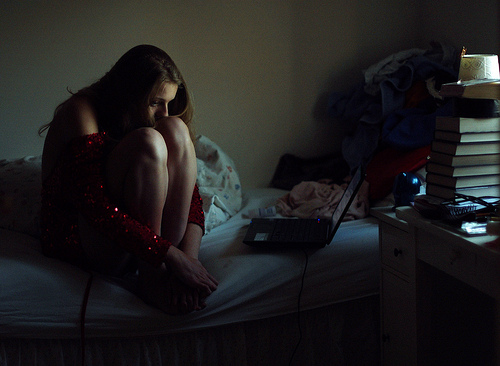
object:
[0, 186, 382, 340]
bed sheet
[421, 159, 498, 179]
books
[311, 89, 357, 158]
shade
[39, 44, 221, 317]
woman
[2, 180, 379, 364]
bed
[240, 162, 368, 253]
laptop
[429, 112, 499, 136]
books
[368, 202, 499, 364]
wooden desk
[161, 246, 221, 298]
hand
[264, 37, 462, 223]
messy pile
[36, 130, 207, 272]
red sequined blouse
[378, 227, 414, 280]
drawer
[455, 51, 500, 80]
top half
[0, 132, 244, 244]
blanket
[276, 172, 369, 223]
clothes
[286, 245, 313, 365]
black wire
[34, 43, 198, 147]
long brown hair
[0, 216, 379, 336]
edge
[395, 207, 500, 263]
edge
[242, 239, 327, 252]
edge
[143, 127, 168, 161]
part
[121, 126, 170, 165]
knee